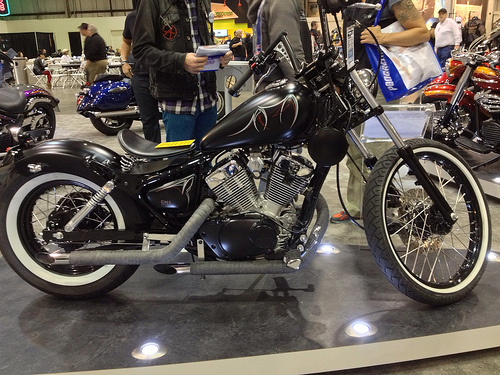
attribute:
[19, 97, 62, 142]
tire — rear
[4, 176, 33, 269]
stripe — white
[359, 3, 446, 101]
shoulder bag — white, blue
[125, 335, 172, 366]
light — on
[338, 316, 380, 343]
light — on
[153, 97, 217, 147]
jeans — blue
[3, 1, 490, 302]
motercycle — black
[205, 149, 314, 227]
motor —  chrome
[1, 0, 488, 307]
motorcycle — black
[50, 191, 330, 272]
exhaust pipes —  chrome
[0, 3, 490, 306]
bike — black, motorized 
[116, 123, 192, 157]
seat — black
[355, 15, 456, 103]
bag — person's shoulder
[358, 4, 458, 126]
bag — person's shoulder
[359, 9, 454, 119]
bag — person's shoulder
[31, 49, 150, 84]
tables — back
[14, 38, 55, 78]
chairs — back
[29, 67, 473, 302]
motorbikes — display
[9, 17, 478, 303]
motorbikes — display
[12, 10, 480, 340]
motorbikes — display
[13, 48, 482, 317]
motorbikes — display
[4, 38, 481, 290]
motorbikes — display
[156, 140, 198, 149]
tag — yellow 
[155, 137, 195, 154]
tag — yellow 